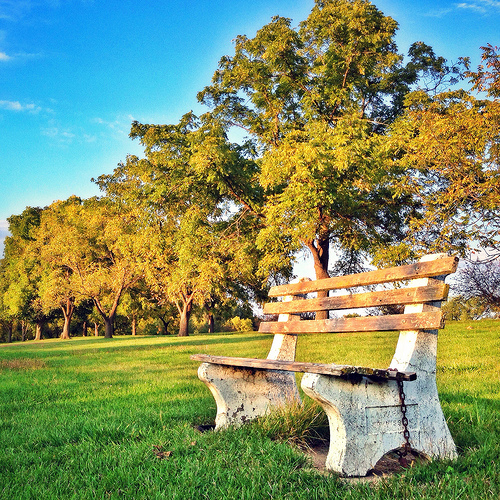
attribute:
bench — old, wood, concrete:
[192, 253, 464, 472]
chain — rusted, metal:
[396, 372, 420, 448]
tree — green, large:
[217, 5, 397, 327]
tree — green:
[397, 87, 494, 310]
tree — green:
[111, 115, 260, 332]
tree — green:
[35, 197, 115, 346]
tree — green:
[4, 208, 44, 339]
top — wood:
[260, 259, 455, 334]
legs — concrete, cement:
[303, 374, 459, 474]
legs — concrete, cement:
[194, 364, 299, 429]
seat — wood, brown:
[191, 351, 416, 383]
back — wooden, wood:
[257, 257, 459, 333]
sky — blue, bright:
[0, 0, 499, 206]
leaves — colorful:
[299, 140, 369, 207]